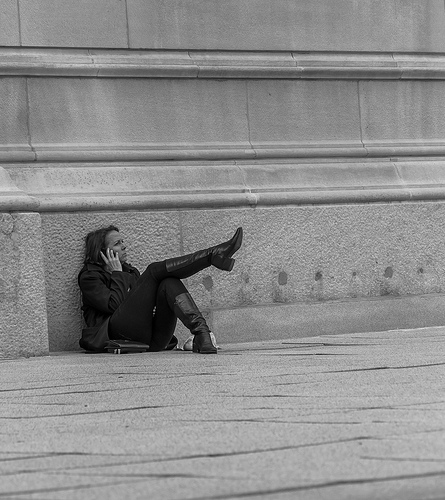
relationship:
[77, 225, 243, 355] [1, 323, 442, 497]
female sitting on sidewalk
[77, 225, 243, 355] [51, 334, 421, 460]
female sitting on sidewalk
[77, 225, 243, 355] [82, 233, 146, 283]
female talking on cellphone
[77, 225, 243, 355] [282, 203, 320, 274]
female leaning against wall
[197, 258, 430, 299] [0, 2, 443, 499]
spots on wall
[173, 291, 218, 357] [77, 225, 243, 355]
boot of female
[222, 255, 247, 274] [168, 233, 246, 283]
heel of boot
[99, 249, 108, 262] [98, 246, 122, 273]
finger of hand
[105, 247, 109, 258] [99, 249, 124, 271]
finger of hand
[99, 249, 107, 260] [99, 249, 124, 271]
finger of hand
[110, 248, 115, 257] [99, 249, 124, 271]
finger of hand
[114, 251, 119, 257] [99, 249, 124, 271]
finger of hand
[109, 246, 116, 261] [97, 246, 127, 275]
finger of hand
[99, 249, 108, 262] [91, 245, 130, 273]
finger of hand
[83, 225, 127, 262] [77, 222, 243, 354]
head of woman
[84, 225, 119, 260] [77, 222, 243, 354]
hair of woman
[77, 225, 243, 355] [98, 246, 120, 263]
female using cell phone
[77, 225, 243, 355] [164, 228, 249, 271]
female wearing boots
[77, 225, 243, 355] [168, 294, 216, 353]
female wearing boots